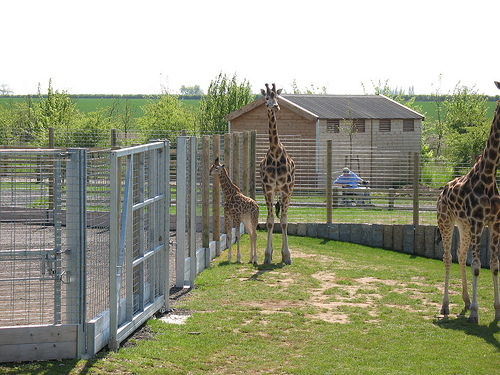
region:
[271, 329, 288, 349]
part of a ground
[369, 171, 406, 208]
part of a fence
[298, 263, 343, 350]
part of a ground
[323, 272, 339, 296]
part of a ground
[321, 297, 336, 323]
part of a ground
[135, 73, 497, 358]
Three giraffes standing on a grassy area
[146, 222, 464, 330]
Patches of grass missing in the field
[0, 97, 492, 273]
A fence keeping the giraffes in a zoo enclosure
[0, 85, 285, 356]
Another area of the enclosure with a fence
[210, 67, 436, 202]
A brick building behind the enclosure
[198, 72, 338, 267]
A baby giraffe standing next to a taller giraffe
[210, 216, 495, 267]
A stone wall lining the enclosure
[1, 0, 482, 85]
A clear sky with no clouds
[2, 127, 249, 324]
A dirt ground covering inside of the enclosure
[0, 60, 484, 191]
Young trees with bright green leaves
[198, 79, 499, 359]
three giraffes standing on the grass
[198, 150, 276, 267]
small baby giraffe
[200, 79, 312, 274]
baby giraffe standing next to an adult one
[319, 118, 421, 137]
row of four windows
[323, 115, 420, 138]
windows on the top of the building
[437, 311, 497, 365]
shadow from the giraffe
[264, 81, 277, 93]
two tiny hrons on the top of the head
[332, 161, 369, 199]
person wearing light blue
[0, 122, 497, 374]
fence around the enclosure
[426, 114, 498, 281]
brown spots on the skin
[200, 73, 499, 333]
group of three giraffes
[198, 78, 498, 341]
giraffes standing on the grass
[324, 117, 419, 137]
four windows on the top of the building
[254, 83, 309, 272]
large adult giraffe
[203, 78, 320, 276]
baby giraffe standing next to an adult giraffe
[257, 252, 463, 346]
patches of dirt on the ground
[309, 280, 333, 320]
part of a ground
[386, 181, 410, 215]
part of a fence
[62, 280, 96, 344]
edge of a fence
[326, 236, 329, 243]
part of a femce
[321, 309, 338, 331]
part of a ground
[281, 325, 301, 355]
part of a chaior